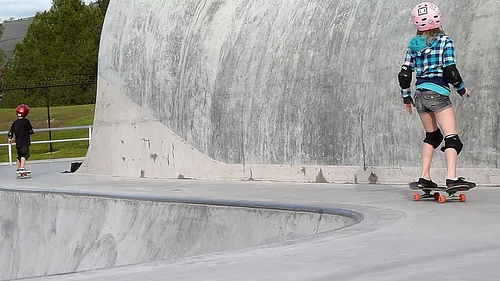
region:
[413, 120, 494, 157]
the kneepad is black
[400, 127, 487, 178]
the kneepad is black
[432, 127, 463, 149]
the kneepad is black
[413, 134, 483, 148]
the kneepad is black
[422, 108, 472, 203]
the kneepad is black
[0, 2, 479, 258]
two kids on skateboards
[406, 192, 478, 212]
red wheels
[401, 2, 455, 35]
girl wearing a pink helmet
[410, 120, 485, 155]
girl wearing protective black knee pads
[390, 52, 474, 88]
girl wearing black protective elbow pads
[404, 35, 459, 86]
checkered blue and white shirt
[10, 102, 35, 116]
boy wearing a red helmet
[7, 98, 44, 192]
boy on a skateboard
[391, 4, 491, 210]
girl on a skateboard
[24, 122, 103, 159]
a silver metal fence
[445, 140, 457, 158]
THE KNEE PAD IS BLACK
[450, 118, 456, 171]
THE KNEE PAD IS BLACK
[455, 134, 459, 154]
THE KNEE PAD IS BLACK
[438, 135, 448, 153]
THE KNEE PAD IS BLACK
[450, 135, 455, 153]
THE KNEE PAD IS BLACK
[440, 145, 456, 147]
THE KNEE PAD IS BLACK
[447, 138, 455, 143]
THE KNEE PAD IS BLACK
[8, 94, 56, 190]
boy wearing red helmet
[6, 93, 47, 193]
boy riding a skateboard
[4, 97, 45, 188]
boy wearing a black shirt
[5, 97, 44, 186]
boy wearing black shorts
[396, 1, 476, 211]
girl wearing pink helmet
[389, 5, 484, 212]
girl wearing checkered blue sweater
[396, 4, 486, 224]
girl wearing short jean shorts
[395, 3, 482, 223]
girl riding a skateboard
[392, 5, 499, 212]
girl wearing black knee pads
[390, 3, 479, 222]
girl wearing black elbow pads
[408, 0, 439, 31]
pink helmet on girl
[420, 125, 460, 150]
black knee pads on girl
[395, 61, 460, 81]
black elbow pads on girl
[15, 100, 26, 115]
red helmet on child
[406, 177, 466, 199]
skateboard with orange wheels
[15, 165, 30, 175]
skateboard with white wheels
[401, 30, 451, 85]
turquoise and white checkered jacket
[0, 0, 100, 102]
large green tree in the background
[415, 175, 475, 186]
black tennis shoes on girl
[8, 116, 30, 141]
black t shirt on child